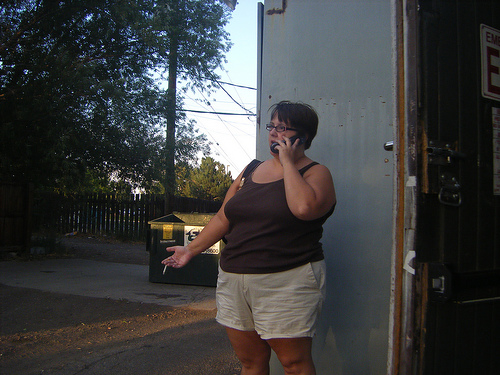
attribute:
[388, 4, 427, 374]
door — wooden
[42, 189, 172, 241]
fence — wooden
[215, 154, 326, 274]
top — tank, brown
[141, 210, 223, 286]
dumpster — green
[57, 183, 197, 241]
fence — wooden